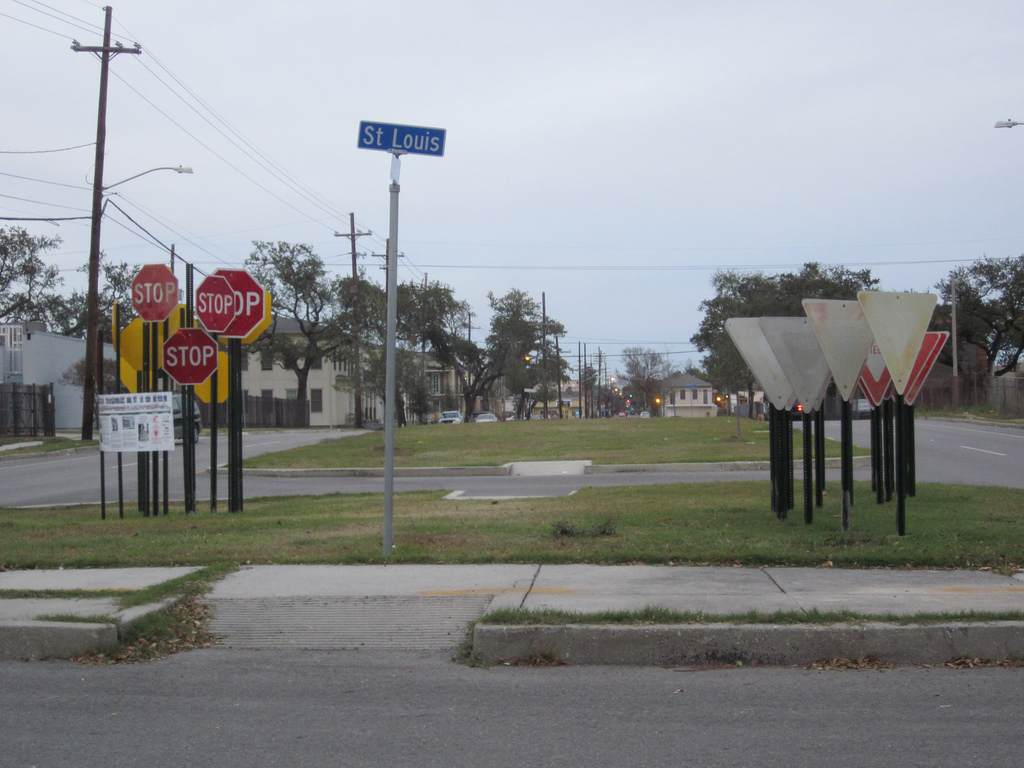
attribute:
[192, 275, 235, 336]
sign — yellow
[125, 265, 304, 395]
signs — red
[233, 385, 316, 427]
fence — wooden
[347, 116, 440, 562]
street sign — tall, blue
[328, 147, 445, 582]
pole — wooden, brown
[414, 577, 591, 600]
line — orange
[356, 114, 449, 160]
sign — St.Louis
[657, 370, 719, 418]
house — cream-colored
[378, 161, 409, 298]
sign — white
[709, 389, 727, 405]
light — bright yellow